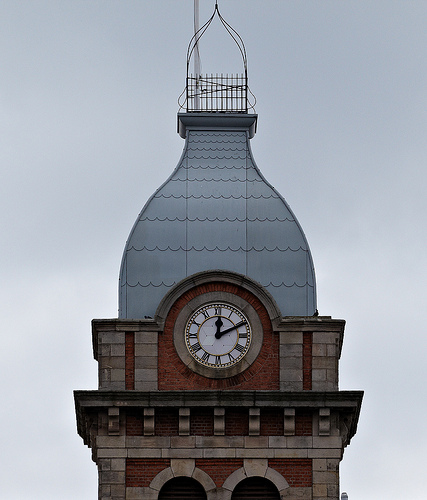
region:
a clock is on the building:
[153, 265, 328, 458]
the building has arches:
[148, 465, 234, 497]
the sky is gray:
[40, 217, 143, 321]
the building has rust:
[139, 433, 241, 491]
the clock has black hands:
[187, 302, 380, 463]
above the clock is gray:
[127, 191, 406, 329]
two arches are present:
[127, 443, 331, 496]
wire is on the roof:
[174, 54, 306, 147]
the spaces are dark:
[159, 466, 204, 488]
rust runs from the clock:
[175, 351, 307, 402]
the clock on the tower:
[183, 301, 251, 368]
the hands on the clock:
[214, 313, 247, 338]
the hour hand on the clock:
[215, 314, 222, 337]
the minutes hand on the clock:
[214, 320, 246, 338]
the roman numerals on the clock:
[186, 306, 248, 365]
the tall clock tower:
[73, 0, 363, 499]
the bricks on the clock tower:
[72, 268, 363, 498]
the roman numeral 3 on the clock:
[238, 331, 248, 338]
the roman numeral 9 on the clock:
[187, 331, 197, 338]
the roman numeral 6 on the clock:
[214, 356, 222, 365]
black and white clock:
[182, 293, 250, 369]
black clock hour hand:
[210, 315, 225, 340]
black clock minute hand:
[220, 317, 247, 342]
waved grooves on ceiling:
[120, 131, 306, 320]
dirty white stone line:
[275, 328, 304, 395]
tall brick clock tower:
[63, 275, 369, 497]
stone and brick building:
[76, 269, 366, 498]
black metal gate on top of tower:
[181, 4, 248, 113]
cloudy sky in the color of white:
[1, 0, 425, 491]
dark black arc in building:
[157, 466, 208, 496]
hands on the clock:
[210, 316, 235, 342]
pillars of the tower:
[89, 392, 339, 436]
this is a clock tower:
[121, 44, 344, 497]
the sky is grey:
[13, 179, 81, 288]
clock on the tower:
[158, 283, 258, 378]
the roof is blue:
[167, 192, 277, 253]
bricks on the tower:
[295, 328, 337, 383]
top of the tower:
[184, 13, 255, 115]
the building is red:
[170, 366, 191, 385]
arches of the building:
[145, 457, 293, 498]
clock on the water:
[142, 264, 259, 373]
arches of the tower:
[145, 464, 288, 498]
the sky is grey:
[383, 426, 396, 481]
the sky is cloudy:
[3, 410, 57, 462]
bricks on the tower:
[277, 319, 328, 390]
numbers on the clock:
[209, 305, 227, 317]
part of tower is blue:
[148, 106, 284, 187]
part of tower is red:
[165, 370, 183, 387]